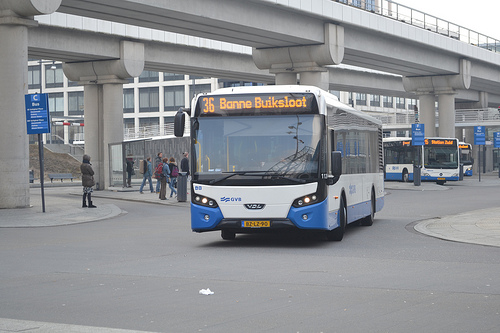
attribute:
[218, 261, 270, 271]
bird — black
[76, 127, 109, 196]
bird — black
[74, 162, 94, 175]
jacket — black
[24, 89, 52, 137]
sign — blue, white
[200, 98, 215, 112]
number — orange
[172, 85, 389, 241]
bus — blue, black, white, parked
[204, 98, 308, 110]
print — orange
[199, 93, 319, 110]
background — black